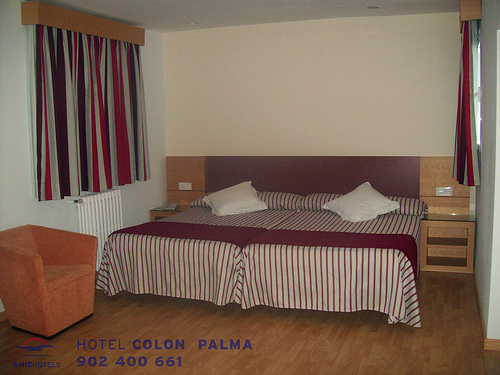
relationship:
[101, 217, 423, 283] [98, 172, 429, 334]
blanket on bed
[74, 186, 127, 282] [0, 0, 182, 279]
radiator on wall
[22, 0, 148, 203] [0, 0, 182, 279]
window on wall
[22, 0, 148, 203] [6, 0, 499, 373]
window in bedroom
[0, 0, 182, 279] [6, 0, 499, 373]
wall in bedroom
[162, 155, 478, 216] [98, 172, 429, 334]
headboard on bed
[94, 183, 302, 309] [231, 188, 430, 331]
bed together with bed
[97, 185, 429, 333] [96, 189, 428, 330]
bedspread with stripes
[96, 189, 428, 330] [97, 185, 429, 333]
stripes on bedspread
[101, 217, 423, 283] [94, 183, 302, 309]
blanket across bed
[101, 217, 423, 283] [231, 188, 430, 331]
blanket across bed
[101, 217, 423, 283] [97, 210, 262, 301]
blanket across bottom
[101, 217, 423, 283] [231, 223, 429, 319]
blanket across bottom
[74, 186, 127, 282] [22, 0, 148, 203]
radiator under window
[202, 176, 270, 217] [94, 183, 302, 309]
pillow on bed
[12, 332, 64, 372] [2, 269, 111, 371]
logo in corner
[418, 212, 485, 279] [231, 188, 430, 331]
nightstand beside bed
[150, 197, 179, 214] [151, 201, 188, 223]
telephone on nightstand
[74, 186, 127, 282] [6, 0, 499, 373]
heat in room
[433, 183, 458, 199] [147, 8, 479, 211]
outlet in wall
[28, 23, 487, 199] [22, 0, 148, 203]
curtains covering window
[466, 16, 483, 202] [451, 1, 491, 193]
light through window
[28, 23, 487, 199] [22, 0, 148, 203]
curtains on window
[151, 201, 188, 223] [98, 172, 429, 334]
nightstand next to bed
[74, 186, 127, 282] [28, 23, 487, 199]
radiator under curtains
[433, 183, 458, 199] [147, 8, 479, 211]
outlet on wall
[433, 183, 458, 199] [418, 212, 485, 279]
outlet above nightstand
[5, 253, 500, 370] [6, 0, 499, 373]
floor in room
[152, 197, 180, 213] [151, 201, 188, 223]
phone sitting on nightstand